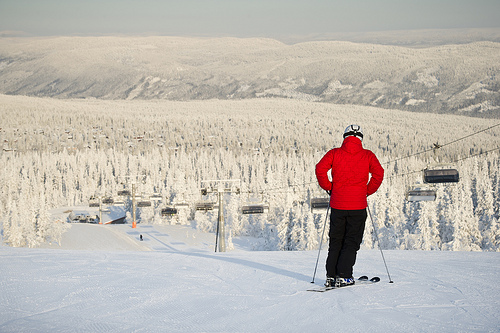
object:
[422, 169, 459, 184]
ski-lift car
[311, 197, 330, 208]
ski-lift car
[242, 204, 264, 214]
ski-lift car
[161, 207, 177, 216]
ski-lift car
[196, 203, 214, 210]
ski-lift car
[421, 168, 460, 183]
bench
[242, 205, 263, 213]
bench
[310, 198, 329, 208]
bench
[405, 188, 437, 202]
bench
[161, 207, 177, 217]
bench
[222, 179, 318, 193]
ski lift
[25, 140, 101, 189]
snow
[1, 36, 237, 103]
mountain range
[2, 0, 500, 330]
area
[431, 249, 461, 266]
ground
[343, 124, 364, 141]
helmet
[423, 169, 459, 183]
seat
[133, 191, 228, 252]
ski lift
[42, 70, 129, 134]
snow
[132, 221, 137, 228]
cone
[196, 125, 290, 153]
snow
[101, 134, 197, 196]
trees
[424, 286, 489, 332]
snow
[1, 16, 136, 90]
mountain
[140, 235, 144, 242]
background person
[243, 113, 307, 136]
wall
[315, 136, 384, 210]
jacket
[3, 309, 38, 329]
snow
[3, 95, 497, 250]
pine trees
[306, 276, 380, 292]
skis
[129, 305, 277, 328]
snow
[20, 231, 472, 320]
ski slope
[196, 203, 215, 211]
cars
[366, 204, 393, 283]
ski pole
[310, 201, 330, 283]
ski pole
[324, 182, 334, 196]
hand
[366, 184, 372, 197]
hand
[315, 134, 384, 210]
red coat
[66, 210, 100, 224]
lodge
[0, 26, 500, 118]
mountains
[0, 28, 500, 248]
landscape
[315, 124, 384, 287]
man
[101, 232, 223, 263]
snow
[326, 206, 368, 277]
pants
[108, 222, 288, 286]
slope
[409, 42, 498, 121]
mountain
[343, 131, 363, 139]
band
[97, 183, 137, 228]
ski lift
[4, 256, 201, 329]
ground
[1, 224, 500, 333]
hill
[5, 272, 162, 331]
tracks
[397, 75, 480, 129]
snow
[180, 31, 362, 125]
mountain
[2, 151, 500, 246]
valley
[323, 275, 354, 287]
feet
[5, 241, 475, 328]
mountain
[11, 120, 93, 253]
lift